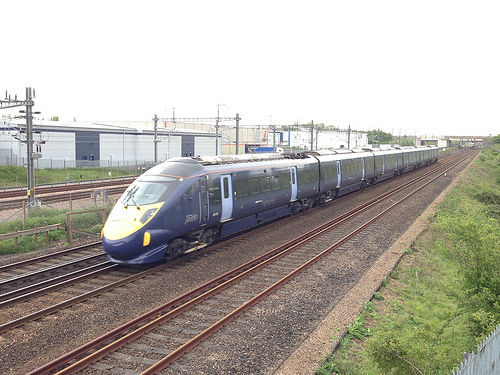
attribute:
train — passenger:
[108, 134, 444, 264]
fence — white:
[456, 345, 498, 370]